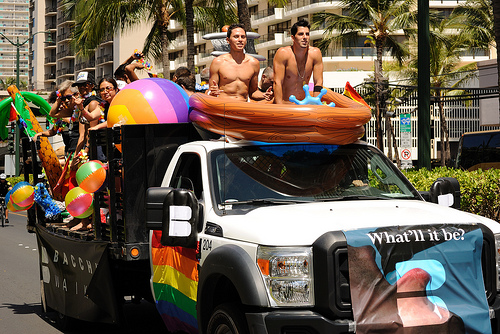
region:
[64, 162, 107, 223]
colorful beach balls on the truck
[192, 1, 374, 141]
two guys in a boat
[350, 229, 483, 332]
banner on front of the truck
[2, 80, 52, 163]
inflatable palm tree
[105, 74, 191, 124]
big beach ball on top of truck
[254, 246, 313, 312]
headlight on the truck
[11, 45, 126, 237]
group of people in a beach scene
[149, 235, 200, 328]
rainbow flag on the side of truck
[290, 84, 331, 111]
blue wheel of the boat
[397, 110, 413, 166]
sign on the pole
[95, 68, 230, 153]
a rainbow beach ball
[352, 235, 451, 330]
a logo on the front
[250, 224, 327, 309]
a head light on the truck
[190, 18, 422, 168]
2 men riding on top of the truck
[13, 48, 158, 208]
a group of people on the back of the truck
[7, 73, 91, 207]
a inflatable palm tree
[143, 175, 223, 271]
side mirror on truck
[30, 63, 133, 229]
several people with beach toys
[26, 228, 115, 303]
a sign hanging from truck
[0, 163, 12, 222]
a person on a bike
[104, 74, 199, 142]
multi color large beach ball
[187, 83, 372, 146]
inflatable ship looking water raft with blue ships wheel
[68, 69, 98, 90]
man's black and white hat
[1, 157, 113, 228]
several small multi colored inflatable beach balls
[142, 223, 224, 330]
rainbow colored banner stuck to truck's door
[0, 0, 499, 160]
several multi story apartment buildings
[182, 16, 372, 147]
two dark haired shirtless men in inflatable boat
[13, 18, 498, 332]
truck full of people with bunches of inflatable beach toys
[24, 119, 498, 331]
white half ton truck with black bed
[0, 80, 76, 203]
inflatable palm tree beach toy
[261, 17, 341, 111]
topless man standing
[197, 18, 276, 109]
topless man standing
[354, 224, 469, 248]
slogan saying what'll it be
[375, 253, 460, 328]
corporate logo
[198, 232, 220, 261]
sign indicating the number two hundred four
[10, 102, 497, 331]
white work truck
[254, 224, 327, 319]
truck headlight -- left side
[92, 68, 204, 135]
rainbow colored beach ball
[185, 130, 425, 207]
truck windshield with driver inside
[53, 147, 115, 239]
two colorful beach balls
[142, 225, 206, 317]
A gay pride rainbow flag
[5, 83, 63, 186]
Inflatable palm tree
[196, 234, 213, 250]
The numbers 204 in black on a pickup truck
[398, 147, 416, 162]
A no parking sign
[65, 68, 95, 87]
A black and white baseball cap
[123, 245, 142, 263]
A round yellow reflector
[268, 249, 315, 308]
The headlights of a truck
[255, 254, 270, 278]
The turn signal indicator of a truck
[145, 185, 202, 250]
The passenger side view mirror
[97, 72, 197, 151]
A large blow up multicolored beach ball